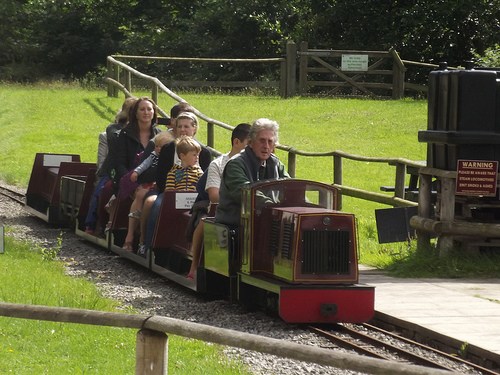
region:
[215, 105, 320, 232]
man with gray hair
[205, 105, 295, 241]
man wearing green jacket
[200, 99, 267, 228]
boy with short hair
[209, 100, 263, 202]
boy with brown hair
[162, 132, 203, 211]
little boy with blond hair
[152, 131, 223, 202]
little boy with striped shirt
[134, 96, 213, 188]
woman with short hair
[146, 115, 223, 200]
woman wearing black jacket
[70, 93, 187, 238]
woman with long dark hair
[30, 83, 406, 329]
several people riding a child's train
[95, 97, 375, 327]
people ride a small train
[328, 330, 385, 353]
the small train tracks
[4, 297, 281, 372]
a wooden hand rail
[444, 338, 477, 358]
a weed by the platform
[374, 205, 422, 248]
a sign in the grass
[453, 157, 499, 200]
a sign on the post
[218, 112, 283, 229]
the train conductor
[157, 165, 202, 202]
A stripped sweater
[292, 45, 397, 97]
a gate for the fence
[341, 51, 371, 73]
a white sign on the gate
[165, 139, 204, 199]
a boy wearing a striped shirt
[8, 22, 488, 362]
A miniature railroad scene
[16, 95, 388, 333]
This is a miniature train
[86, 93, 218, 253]
People are riding the train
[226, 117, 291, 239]
This man is driving the train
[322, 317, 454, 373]
These are the train tracks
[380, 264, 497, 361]
A wooden platform is next to the tracks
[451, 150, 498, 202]
This is a warning sign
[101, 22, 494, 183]
A wooden fence is surrounding this area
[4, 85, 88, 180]
A grassy area is behind the train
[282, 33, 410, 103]
The fence has a gate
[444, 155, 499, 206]
red and white warning sign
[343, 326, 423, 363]
triple railroad tracks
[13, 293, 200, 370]
wooden fence posts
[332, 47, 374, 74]
white sign on wooden gate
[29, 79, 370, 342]
people on a children's train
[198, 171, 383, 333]
red train engine on tracks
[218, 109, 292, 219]
man in grey jacket driving train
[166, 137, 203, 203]
boy wearing a yellow and brown striped shirt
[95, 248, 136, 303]
gravel beside train tracks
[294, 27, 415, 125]
brown wooden gate